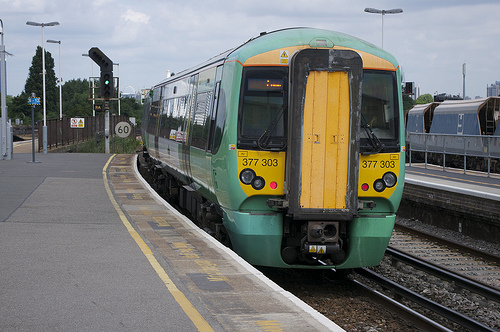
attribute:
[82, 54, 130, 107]
light — red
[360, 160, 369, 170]
number — black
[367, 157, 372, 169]
number — black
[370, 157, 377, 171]
number — black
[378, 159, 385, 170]
number — black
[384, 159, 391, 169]
number — black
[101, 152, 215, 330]
line — yellow, painted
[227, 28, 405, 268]
front — yellow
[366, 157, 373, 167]
number — black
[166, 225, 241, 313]
words — yellow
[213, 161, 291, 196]
light — off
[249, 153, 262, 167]
number — black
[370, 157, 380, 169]
number — black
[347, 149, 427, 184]
number — black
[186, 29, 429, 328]
train — green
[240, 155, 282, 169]
number — black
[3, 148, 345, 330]
sidewalk — gray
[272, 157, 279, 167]
number — black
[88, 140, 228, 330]
line — yellow, painted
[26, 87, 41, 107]
sign — blue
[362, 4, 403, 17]
light — off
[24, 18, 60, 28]
light — off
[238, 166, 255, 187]
light — off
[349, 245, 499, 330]
track — steel